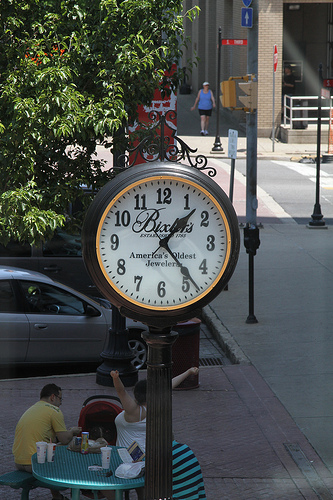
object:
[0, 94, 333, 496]
floor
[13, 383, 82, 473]
man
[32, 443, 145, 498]
table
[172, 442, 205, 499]
person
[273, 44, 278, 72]
stop sign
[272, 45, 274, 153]
pole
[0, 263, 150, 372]
car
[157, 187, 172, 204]
number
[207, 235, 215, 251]
number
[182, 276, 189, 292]
number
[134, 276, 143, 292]
number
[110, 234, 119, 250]
number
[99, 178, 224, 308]
glass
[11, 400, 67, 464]
shirt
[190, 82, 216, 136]
person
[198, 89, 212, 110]
blue top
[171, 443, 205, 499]
shirt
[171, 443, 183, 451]
stipe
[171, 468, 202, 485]
stipe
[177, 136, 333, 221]
sunshine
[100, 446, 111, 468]
beverage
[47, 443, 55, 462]
beverage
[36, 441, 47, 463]
beverage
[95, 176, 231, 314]
circle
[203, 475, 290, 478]
crack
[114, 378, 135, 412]
arm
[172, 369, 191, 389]
arm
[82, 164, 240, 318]
clock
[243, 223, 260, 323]
parking meter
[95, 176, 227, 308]
face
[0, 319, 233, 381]
parking space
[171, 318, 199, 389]
garbage can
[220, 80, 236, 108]
crosswalk signal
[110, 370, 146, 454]
woman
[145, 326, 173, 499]
pole